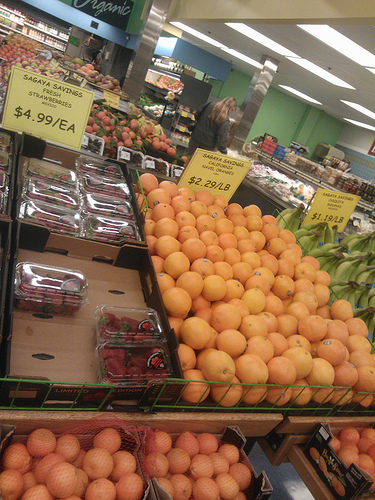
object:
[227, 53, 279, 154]
pillar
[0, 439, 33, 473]
oranges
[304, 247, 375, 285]
banana row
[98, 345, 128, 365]
strawberries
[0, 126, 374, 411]
shelf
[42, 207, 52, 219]
strawberries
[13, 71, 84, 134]
sign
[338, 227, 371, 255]
bananas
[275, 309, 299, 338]
oranges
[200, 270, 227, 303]
oranges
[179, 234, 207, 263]
oranges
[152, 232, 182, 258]
oranges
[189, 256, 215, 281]
oranges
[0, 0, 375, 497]
store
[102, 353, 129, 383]
strawberries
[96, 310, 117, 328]
strawberries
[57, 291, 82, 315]
strawberries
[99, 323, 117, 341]
strawberries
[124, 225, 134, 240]
strawberries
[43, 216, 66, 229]
strawberries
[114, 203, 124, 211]
strawberries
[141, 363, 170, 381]
strawberries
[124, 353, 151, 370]
strawberries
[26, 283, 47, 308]
strawberries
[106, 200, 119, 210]
strawberries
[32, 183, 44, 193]
strawberries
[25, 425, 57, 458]
oranges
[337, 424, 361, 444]
oranges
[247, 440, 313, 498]
ground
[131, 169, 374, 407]
group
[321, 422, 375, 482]
group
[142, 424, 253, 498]
group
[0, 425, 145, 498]
group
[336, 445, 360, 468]
oranges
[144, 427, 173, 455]
oranges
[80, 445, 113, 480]
oranges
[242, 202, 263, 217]
oranges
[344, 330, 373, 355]
oranges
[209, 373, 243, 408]
oranges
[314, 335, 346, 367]
oranges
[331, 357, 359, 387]
oranges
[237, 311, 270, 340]
oranges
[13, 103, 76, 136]
price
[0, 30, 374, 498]
produce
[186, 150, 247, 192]
sign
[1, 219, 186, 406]
cardboard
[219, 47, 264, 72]
light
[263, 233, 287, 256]
oranges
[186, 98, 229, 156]
sweater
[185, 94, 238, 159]
lady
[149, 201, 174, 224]
orange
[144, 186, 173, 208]
orange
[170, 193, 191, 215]
orange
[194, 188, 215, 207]
orange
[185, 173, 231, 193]
price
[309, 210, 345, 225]
price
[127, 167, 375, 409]
display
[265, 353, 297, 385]
orange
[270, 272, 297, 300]
orange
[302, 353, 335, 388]
orange